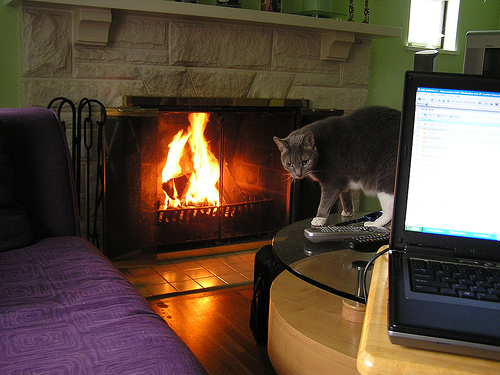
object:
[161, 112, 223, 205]
fire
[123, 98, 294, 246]
fireplace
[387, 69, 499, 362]
laptop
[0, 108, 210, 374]
couch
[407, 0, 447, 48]
window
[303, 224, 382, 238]
remote control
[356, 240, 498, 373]
tv table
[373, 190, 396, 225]
leg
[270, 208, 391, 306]
coffee table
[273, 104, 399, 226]
cat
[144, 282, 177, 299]
tile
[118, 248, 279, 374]
floor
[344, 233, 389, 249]
remote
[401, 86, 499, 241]
screen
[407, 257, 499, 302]
keyboard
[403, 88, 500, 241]
browser window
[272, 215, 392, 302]
table top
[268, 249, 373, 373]
base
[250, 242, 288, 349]
suitcase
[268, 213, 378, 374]
table